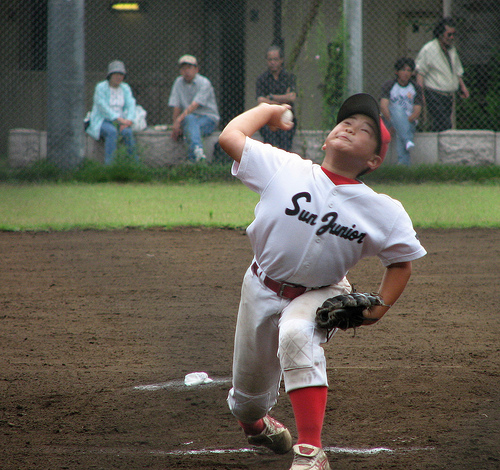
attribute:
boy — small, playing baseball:
[219, 92, 427, 469]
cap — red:
[336, 93, 391, 172]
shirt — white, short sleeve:
[231, 136, 427, 289]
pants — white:
[227, 259, 353, 422]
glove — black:
[316, 289, 386, 342]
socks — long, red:
[235, 381, 328, 452]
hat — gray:
[105, 57, 125, 80]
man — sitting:
[167, 52, 221, 161]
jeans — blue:
[100, 120, 137, 168]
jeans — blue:
[182, 109, 215, 160]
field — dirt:
[1, 224, 499, 470]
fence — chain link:
[0, 0, 498, 186]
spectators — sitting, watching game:
[84, 41, 423, 164]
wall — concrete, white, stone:
[13, 128, 499, 167]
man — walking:
[411, 14, 468, 131]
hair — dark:
[432, 17, 456, 41]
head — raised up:
[318, 90, 391, 176]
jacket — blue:
[86, 79, 136, 140]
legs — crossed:
[178, 107, 217, 165]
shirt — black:
[255, 67, 296, 112]